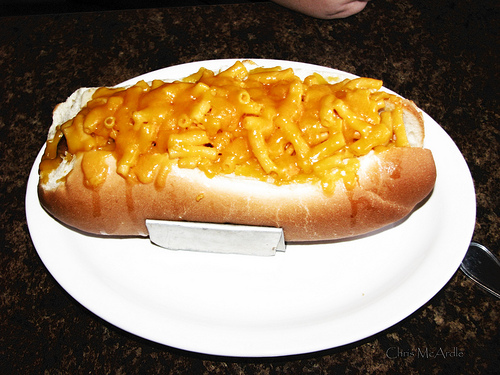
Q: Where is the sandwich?
A: Plate.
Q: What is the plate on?
A: Counter.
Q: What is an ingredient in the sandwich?
A: Macaroni.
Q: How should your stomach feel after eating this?
A: Full.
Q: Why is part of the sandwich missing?
A: Bite is out of it.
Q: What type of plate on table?
A: A white plate.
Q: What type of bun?
A: A brown hot dog bun.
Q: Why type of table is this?
A: A dark marble table.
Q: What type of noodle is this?
A: Mac and cheese noodles.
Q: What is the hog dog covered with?
A: Mac and cheese.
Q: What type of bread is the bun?
A: White bread.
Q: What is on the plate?
A: A hot dog covered with mac and cheese.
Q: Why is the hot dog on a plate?
A: Waiting to be served.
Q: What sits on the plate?
A: Hot dog.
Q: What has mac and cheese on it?
A: Hot dog.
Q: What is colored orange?
A: Mac and cheese.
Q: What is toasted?
A: The bun.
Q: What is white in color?
A: The plate.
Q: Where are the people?
A: No people.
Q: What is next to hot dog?
A: Piece of paper.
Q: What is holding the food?
A: A plate.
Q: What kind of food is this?
A: A hotdog.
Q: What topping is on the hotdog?
A: Macaroni and cheese.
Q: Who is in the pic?
A: No one.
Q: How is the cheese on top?
A: Melted.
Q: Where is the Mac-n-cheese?
A: In bun.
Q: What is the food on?
A: Plate.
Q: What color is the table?
A: Black.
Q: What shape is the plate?
A: Round.